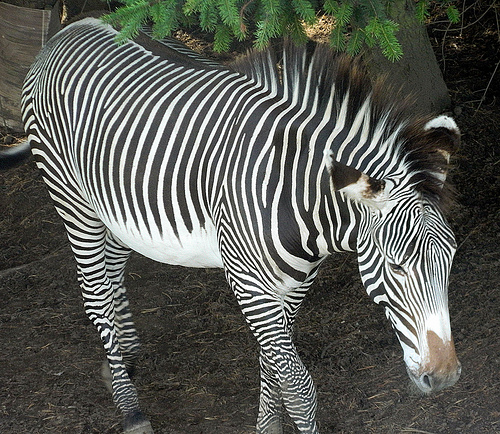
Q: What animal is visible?
A: Zebra.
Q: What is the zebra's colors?
A: Black and white.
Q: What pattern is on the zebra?
A: Stripes.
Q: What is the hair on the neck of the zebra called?
A: Mane.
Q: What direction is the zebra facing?
A: Right.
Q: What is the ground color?
A: Brown.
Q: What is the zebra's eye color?
A: Black.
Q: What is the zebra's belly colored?
A: White.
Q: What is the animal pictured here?
A: A zebra.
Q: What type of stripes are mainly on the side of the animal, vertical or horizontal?
A: Vertical.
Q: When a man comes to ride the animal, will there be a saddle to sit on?
A: No.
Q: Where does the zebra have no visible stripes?
A: Belly.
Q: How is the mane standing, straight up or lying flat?
A: Straight up.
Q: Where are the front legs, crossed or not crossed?
A: Crossed.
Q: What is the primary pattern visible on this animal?
A: Stripes.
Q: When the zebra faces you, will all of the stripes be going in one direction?
A: No.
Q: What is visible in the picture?
A: One zebra.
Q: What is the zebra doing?
A: It's standing.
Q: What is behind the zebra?
A: A tree.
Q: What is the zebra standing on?
A: Brown dirt.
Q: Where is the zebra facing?
A: To the right.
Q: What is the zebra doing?
A: Walking on the dirt.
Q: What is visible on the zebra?
A: Black and white stripes.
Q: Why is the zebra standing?
A: It's walking.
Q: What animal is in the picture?
A: A zebra.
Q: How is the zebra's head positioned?
A: Looking at the ground.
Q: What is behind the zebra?
A: A pine tree.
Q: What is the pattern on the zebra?
A: Black and white stripes.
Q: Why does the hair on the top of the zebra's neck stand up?
A: It is the zebra's mane.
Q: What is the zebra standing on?
A: A grassy area.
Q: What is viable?
A: A zebra.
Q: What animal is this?
A: A zebra.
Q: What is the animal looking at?
A: The ground.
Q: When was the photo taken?
A: Daytime.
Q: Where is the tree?
A: Behind the animal.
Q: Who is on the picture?
A: No one.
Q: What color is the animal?
A: Black and white.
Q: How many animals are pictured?
A: One.